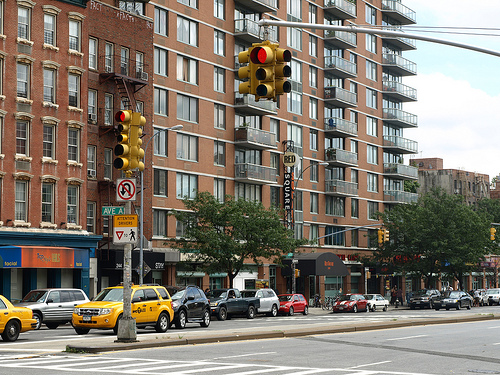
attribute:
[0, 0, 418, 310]
building — tall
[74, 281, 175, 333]
taxi — moving, yellow, waiting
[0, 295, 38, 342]
taxi — moving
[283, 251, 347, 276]
awning — black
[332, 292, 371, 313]
car — red, parked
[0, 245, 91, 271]
awning — red, blue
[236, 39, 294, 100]
traffic light — yellow, hanging, red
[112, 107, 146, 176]
traffic light — yellow, red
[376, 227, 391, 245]
traffic light — yellow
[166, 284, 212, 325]
car — moving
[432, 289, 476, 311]
car — moving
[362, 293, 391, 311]
car — parked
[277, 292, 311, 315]
car — parked, red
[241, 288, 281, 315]
car — parked, silver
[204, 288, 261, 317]
car — parked, black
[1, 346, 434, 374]
crosswalk — empty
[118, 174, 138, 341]
pole — silver